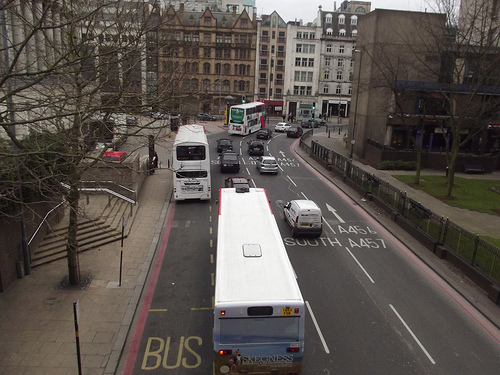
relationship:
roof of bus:
[214, 187, 307, 306] [214, 189, 321, 374]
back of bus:
[213, 307, 303, 374] [214, 189, 321, 374]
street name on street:
[284, 237, 386, 249] [116, 121, 500, 372]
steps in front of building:
[30, 192, 136, 268] [0, 4, 94, 285]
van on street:
[282, 196, 323, 237] [116, 121, 500, 372]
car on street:
[275, 121, 293, 133] [116, 121, 500, 372]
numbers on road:
[346, 235, 387, 251] [114, 126, 499, 372]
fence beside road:
[298, 127, 500, 300] [114, 126, 499, 372]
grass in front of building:
[395, 173, 499, 216] [347, 8, 499, 172]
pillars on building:
[3, 2, 75, 76] [0, 4, 94, 285]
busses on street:
[173, 102, 306, 374] [116, 121, 500, 372]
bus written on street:
[140, 335, 205, 370] [116, 121, 500, 372]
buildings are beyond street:
[77, 1, 370, 121] [116, 121, 500, 372]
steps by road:
[30, 192, 136, 268] [114, 126, 499, 372]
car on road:
[256, 155, 278, 175] [114, 126, 499, 372]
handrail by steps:
[56, 179, 137, 218] [30, 192, 136, 268]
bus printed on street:
[140, 335, 205, 370] [116, 121, 500, 372]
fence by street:
[298, 127, 500, 300] [116, 121, 500, 372]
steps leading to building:
[30, 192, 136, 268] [0, 4, 94, 285]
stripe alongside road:
[119, 200, 177, 373] [114, 126, 499, 372]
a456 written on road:
[339, 225, 377, 236] [114, 126, 499, 372]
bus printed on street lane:
[140, 335, 205, 370] [117, 135, 211, 374]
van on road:
[282, 196, 323, 237] [114, 126, 499, 372]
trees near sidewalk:
[357, 0, 498, 197] [306, 129, 500, 240]